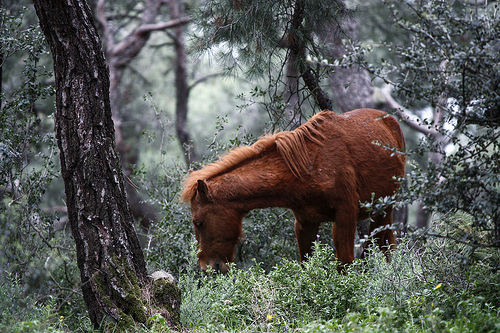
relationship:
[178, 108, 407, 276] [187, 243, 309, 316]
horse grazing on plants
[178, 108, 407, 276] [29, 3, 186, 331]
horse eating by dark tree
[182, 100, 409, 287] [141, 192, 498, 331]
horse by vegetation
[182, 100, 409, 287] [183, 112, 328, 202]
horse with hair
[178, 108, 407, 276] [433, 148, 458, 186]
horse photoshopped ground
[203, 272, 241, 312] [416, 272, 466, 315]
grasses in weeds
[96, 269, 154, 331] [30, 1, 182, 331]
moss on bottom of tree trunk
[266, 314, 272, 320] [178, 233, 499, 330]
dandy lion among plants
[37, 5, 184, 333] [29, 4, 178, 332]
bark on tree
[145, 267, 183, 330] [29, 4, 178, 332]
stone beside tree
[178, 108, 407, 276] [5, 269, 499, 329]
horse in grass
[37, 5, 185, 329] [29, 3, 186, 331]
bark on dark tree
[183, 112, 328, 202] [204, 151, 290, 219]
hair along neck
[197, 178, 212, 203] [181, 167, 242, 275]
ear sticking up off head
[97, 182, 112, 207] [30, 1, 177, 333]
white spot on tree trunk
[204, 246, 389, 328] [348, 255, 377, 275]
plant seen part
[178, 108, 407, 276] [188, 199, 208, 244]
horse has part